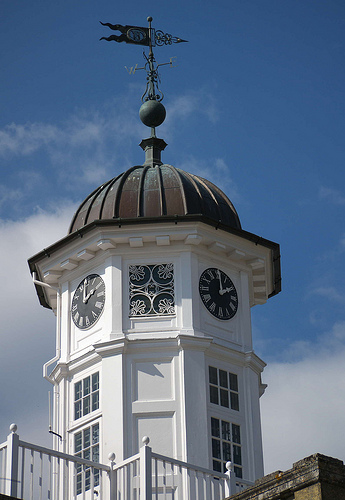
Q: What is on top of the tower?
A: Compass.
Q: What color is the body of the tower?
A: White.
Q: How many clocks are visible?
A: Two.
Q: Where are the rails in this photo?
A: Bottom of the picture.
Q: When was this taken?
A: Daytime.